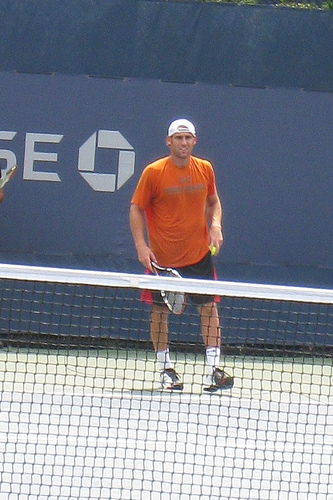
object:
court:
[0, 3, 332, 498]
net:
[0, 262, 333, 499]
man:
[128, 117, 235, 399]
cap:
[166, 115, 201, 140]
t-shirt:
[132, 154, 219, 272]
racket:
[147, 259, 190, 322]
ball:
[210, 243, 218, 255]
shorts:
[140, 251, 223, 310]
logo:
[0, 128, 136, 194]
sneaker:
[159, 364, 185, 392]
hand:
[208, 225, 226, 253]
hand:
[138, 246, 159, 273]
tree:
[202, 1, 332, 14]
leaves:
[320, 0, 331, 15]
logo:
[156, 173, 208, 201]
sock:
[202, 346, 223, 372]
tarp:
[0, 1, 332, 352]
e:
[22, 129, 64, 188]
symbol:
[77, 128, 136, 199]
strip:
[0, 260, 332, 305]